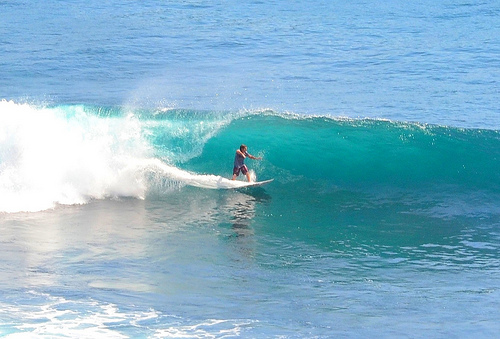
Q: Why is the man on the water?
A: He is surfing.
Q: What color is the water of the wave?
A: Green.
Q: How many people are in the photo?
A: One.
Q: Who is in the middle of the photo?
A: A man.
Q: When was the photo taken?
A: In the daytime.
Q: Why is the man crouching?
A: He is trying to keep his balance.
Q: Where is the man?
A: On the water.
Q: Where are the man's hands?
A: In front of him.